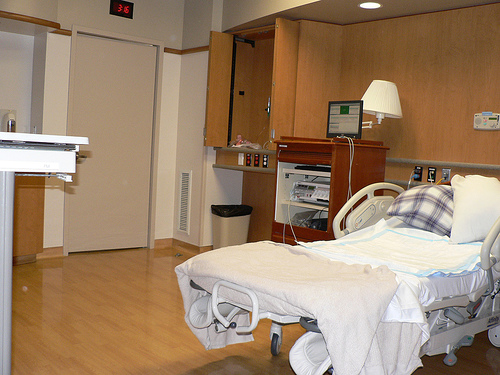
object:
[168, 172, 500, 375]
bed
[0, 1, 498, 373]
room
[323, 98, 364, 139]
monitor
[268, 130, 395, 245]
cabinet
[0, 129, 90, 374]
table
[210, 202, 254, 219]
liner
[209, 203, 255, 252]
trash can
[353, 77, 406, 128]
lamp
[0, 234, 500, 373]
floor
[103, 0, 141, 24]
clock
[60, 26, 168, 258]
door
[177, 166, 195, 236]
air vent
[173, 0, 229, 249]
wall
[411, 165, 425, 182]
outlets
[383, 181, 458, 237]
pillow case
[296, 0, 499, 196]
wall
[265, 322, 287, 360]
wheel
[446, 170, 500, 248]
pillow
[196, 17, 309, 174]
storage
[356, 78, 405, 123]
shade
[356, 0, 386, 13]
light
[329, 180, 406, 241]
rail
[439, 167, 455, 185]
plugs and wires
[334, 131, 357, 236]
wires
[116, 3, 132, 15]
numbers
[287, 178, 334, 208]
electronics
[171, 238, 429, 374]
blanket